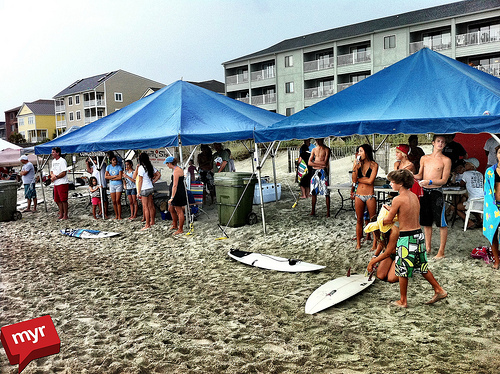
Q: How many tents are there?
A: 2.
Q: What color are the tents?
A: Blue.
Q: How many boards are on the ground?
A: 3.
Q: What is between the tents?
A: A trash can.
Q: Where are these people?
A: At a beach.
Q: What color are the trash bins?
A: Dark green.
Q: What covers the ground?
A: Sand.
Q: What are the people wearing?
A: Swimsuits.